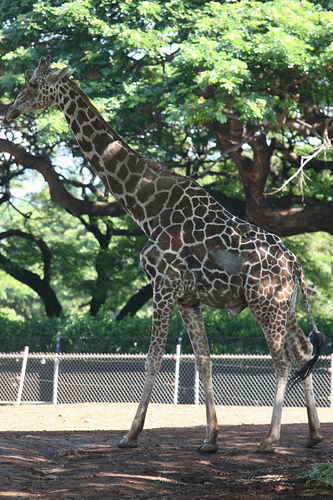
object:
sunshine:
[8, 165, 97, 222]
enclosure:
[0, 352, 329, 406]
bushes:
[0, 315, 331, 350]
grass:
[298, 460, 331, 488]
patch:
[296, 453, 333, 489]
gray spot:
[204, 236, 244, 273]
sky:
[23, 178, 44, 190]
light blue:
[13, 185, 23, 198]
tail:
[284, 258, 326, 396]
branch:
[205, 112, 333, 238]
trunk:
[0, 254, 67, 323]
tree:
[0, 228, 65, 319]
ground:
[143, 46, 170, 69]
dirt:
[0, 404, 332, 497]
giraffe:
[6, 53, 324, 454]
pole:
[15, 344, 29, 405]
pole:
[193, 352, 198, 402]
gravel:
[0, 403, 330, 422]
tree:
[53, 150, 145, 317]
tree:
[113, 280, 154, 323]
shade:
[1, 419, 333, 498]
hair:
[281, 332, 326, 396]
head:
[6, 53, 75, 121]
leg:
[175, 302, 218, 441]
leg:
[127, 288, 176, 434]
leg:
[250, 309, 295, 454]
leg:
[287, 311, 320, 431]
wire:
[4, 331, 323, 347]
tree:
[1, 2, 318, 238]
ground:
[1, 402, 322, 498]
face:
[5, 67, 54, 122]